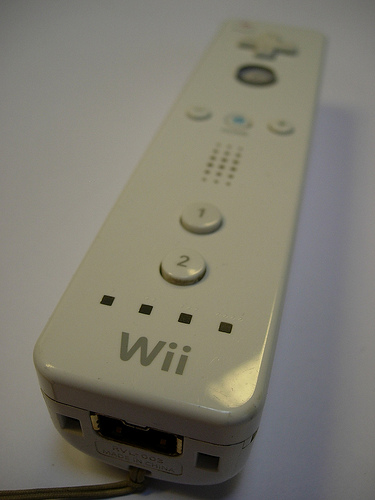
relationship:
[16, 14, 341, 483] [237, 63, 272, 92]
wii remote has home button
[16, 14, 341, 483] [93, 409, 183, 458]
wii remote has usb port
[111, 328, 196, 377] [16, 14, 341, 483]
wii logo written on wii remote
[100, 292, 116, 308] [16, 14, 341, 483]
power light on bottom of wii remote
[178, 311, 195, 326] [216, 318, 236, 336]
power light next to power light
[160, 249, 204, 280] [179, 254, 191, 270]
button has number 2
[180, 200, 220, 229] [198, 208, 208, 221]
button has number 1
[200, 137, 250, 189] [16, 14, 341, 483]
speaker on top of wii remote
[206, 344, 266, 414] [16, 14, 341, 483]
light reflection on bottom of wii remote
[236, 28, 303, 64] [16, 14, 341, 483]
directional button on top of wii remote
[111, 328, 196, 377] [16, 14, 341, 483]
wii logo on bottom of wii remote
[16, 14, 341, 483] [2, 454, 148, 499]
wii remote has strap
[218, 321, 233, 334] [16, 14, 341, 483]
power light on bottom of wii remote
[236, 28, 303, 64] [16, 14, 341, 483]
directional button on far end of wii remote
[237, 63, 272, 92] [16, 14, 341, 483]
home button on top of wii remote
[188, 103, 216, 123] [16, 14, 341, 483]
minus button on top of wii remote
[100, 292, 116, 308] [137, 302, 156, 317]
power light next to power light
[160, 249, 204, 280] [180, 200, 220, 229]
button next to button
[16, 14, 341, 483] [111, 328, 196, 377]
wii remote has wii logo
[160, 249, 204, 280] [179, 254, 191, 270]
button says number 2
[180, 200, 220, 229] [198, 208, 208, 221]
button says number 1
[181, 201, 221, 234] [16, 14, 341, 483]
button on top of wii remote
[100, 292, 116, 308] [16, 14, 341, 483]
power light on wii remote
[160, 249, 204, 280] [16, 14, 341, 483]
button on top of wii remote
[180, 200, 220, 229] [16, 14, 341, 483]
button on top of wii remote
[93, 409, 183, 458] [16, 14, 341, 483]
usb port on bottom of wii remote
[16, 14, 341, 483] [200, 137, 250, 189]
wii remote has speaker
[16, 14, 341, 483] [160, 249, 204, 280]
wii remote has button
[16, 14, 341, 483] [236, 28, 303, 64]
wii remote has directional button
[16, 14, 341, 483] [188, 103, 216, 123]
wii remote has minus button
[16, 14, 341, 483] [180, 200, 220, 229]
wii remote has button